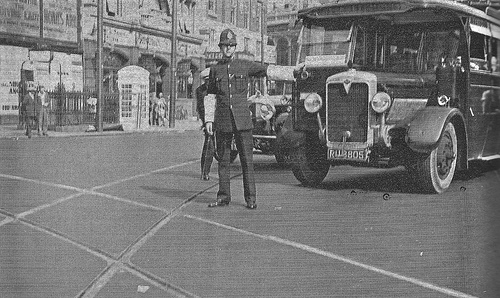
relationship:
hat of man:
[217, 29, 237, 46] [204, 28, 304, 208]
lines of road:
[57, 184, 155, 275] [163, 240, 279, 289]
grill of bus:
[322, 76, 382, 156] [265, 3, 484, 196]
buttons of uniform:
[227, 60, 237, 112] [194, 55, 296, 210]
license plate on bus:
[327, 146, 372, 161] [265, 3, 484, 196]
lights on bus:
[300, 85, 389, 122] [282, 4, 484, 202]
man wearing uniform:
[204, 28, 304, 208] [194, 53, 292, 201]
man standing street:
[204, 28, 304, 208] [5, 145, 178, 289]